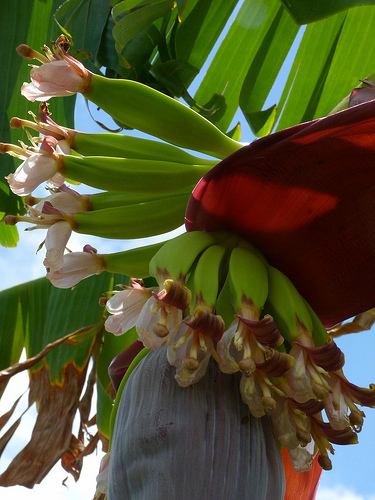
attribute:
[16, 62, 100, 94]
flower — white, pink, green, purple, orange, large, unripened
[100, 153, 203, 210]
leaves — dry, green, red, dead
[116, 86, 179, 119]
stem — green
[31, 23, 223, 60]
banana — flat, green, bottom